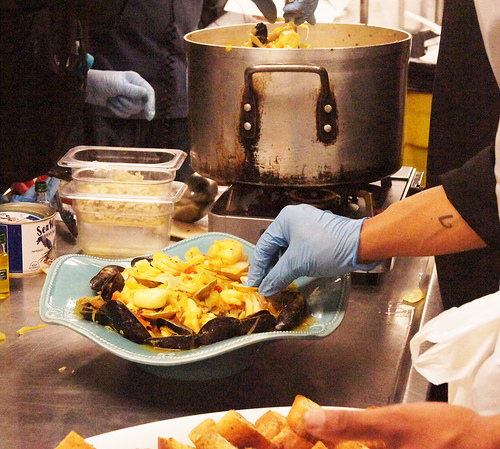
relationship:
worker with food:
[254, 157, 484, 290] [132, 246, 267, 319]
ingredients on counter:
[1, 196, 57, 296] [30, 195, 405, 445]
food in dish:
[77, 176, 165, 226] [79, 175, 167, 254]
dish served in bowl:
[37, 230, 351, 382] [23, 205, 357, 386]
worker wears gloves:
[245, 7, 497, 444] [234, 189, 373, 300]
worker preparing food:
[245, 7, 497, 444] [54, 232, 308, 355]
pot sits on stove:
[178, 18, 430, 188] [192, 145, 427, 241]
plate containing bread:
[85, 406, 368, 447] [60, 396, 349, 445]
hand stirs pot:
[257, 0, 319, 26] [178, 18, 430, 188]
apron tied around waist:
[405, 297, 497, 409] [411, 251, 498, 395]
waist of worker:
[411, 251, 498, 395] [247, 0, 492, 403]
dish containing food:
[37, 230, 351, 382] [75, 233, 332, 353]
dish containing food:
[27, 240, 372, 380] [89, 232, 294, 353]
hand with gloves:
[76, 63, 162, 130] [72, 55, 174, 123]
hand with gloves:
[235, 183, 395, 309] [242, 175, 367, 319]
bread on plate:
[213, 406, 279, 446] [83, 403, 369, 446]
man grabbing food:
[241, 0, 499, 447] [75, 236, 314, 348]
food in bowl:
[75, 236, 314, 348] [39, 232, 349, 378]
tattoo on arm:
[439, 213, 452, 228] [245, 130, 498, 296]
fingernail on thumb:
[303, 405, 325, 426] [297, 402, 477, 446]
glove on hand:
[245, 203, 383, 293] [246, 199, 346, 298]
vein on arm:
[415, 213, 460, 253] [245, 130, 498, 296]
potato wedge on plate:
[216, 410, 276, 446] [83, 403, 369, 446]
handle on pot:
[239, 63, 333, 143] [178, 18, 430, 188]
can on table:
[0, 202, 59, 276] [0, 210, 440, 446]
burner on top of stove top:
[277, 184, 346, 210] [210, 163, 415, 218]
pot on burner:
[178, 18, 430, 188] [282, 188, 343, 208]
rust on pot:
[198, 61, 390, 187] [178, 18, 430, 188]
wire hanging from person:
[148, 20, 179, 150] [46, 21, 226, 169]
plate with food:
[85, 406, 368, 445] [57, 429, 96, 446]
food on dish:
[75, 236, 314, 348] [37, 230, 351, 382]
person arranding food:
[245, 134, 499, 442] [75, 236, 314, 348]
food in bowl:
[91, 254, 303, 343] [32, 254, 358, 384]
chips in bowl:
[143, 267, 265, 318] [56, 231, 383, 351]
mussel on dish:
[269, 288, 313, 333] [37, 230, 351, 382]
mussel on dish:
[89, 265, 124, 289] [37, 230, 351, 382]